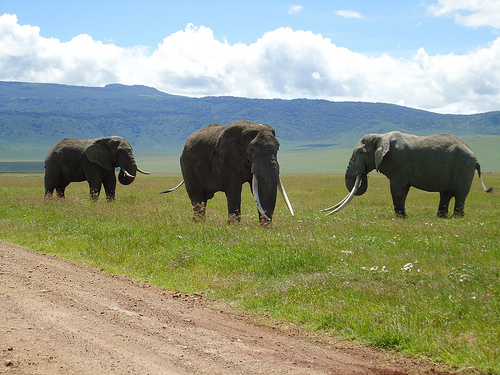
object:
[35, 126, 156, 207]
elephant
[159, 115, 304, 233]
elephant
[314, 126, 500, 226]
elephant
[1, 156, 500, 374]
ground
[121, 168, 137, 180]
tusk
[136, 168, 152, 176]
tusk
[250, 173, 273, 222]
tusk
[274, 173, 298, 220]
tusk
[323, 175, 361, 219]
tusk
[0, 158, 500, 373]
grass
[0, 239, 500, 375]
road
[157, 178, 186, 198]
tail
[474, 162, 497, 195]
tail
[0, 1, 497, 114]
sky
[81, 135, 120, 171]
ear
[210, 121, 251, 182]
ear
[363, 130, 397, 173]
ear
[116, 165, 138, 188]
trunk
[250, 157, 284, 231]
trunk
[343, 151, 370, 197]
trunk